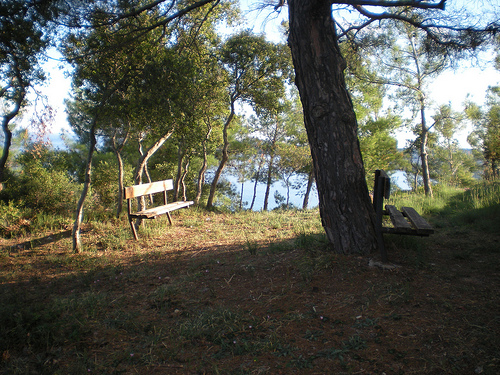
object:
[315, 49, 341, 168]
bark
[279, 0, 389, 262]
tree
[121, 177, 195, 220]
seat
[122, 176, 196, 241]
bench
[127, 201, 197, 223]
boards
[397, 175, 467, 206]
grass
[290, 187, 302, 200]
water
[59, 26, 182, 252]
trees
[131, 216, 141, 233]
legs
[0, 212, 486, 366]
shadows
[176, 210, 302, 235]
sand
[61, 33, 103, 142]
leaves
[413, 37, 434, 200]
trunk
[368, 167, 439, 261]
bench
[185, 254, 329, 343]
path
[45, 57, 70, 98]
sky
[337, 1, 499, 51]
branch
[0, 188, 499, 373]
ground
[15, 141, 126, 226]
shrubs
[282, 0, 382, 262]
trunk